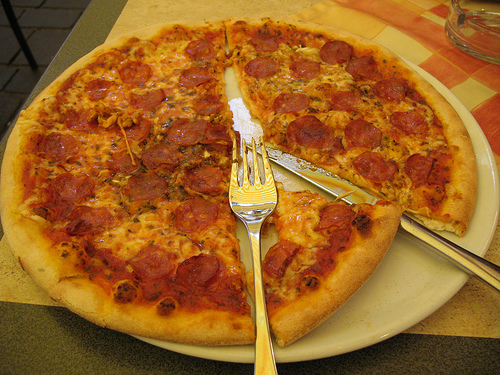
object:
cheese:
[93, 192, 201, 275]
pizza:
[0, 12, 478, 346]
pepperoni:
[172, 251, 221, 292]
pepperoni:
[167, 193, 216, 234]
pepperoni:
[280, 112, 330, 157]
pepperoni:
[180, 161, 227, 198]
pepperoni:
[126, 87, 163, 109]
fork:
[226, 137, 280, 375]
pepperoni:
[118, 168, 168, 203]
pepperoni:
[271, 92, 311, 114]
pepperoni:
[340, 115, 382, 150]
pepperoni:
[317, 40, 356, 68]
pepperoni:
[187, 91, 222, 118]